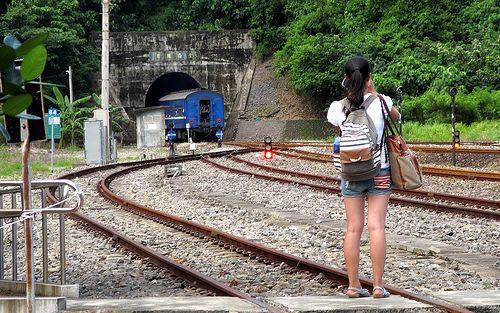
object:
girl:
[327, 57, 400, 295]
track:
[46, 140, 474, 312]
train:
[157, 88, 226, 138]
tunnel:
[146, 73, 201, 108]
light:
[265, 137, 273, 158]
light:
[454, 130, 460, 149]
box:
[85, 119, 116, 165]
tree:
[43, 87, 92, 146]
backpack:
[334, 92, 380, 183]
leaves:
[0, 31, 49, 116]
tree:
[0, 1, 101, 144]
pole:
[101, 2, 108, 107]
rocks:
[1, 137, 347, 298]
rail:
[1, 179, 83, 282]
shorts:
[341, 166, 392, 196]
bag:
[378, 93, 423, 190]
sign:
[45, 114, 61, 138]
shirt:
[327, 93, 393, 170]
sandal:
[348, 286, 370, 297]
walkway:
[66, 288, 499, 310]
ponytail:
[343, 55, 369, 108]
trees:
[1, 0, 497, 57]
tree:
[19, 67, 36, 310]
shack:
[133, 105, 167, 150]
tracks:
[46, 138, 500, 311]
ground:
[0, 142, 499, 312]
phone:
[342, 76, 349, 88]